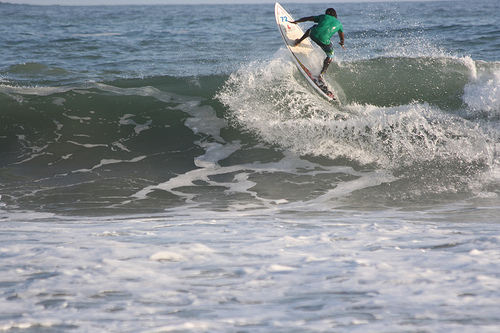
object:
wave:
[1, 50, 497, 180]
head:
[323, 6, 340, 19]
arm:
[293, 14, 320, 23]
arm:
[337, 28, 345, 46]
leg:
[318, 43, 335, 73]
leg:
[297, 25, 317, 46]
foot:
[295, 38, 301, 46]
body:
[289, 7, 346, 81]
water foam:
[170, 152, 308, 191]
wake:
[216, 47, 493, 161]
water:
[0, 212, 497, 330]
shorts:
[306, 27, 336, 57]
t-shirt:
[307, 13, 344, 44]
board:
[272, 2, 341, 104]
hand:
[287, 20, 297, 24]